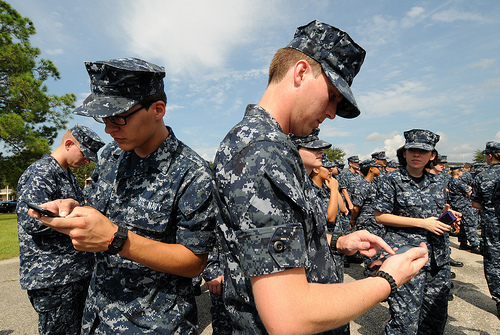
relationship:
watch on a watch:
[94, 217, 158, 287] [103, 225, 131, 255]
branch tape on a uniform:
[136, 198, 166, 209] [27, 55, 215, 335]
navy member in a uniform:
[371, 127, 463, 335] [373, 127, 453, 335]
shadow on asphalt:
[451, 242, 489, 332] [396, 235, 498, 335]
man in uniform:
[16, 126, 103, 334] [17, 126, 101, 334]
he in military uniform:
[30, 53, 220, 333] [86, 126, 213, 333]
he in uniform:
[212, 18, 425, 335] [209, 21, 434, 333]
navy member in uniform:
[371, 127, 463, 335] [373, 127, 453, 335]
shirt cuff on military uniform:
[233, 223, 313, 275] [216, 16, 382, 333]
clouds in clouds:
[12, 5, 498, 175] [12, 5, 499, 160]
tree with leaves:
[0, 0, 76, 184] [0, 0, 75, 182]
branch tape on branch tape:
[139, 195, 163, 212] [139, 195, 163, 212]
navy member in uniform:
[371, 127, 463, 335] [146, 19, 359, 296]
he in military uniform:
[212, 18, 425, 335] [216, 102, 337, 335]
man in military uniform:
[16, 126, 103, 334] [15, 156, 95, 291]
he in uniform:
[212, 18, 425, 335] [225, 80, 347, 263]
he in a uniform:
[212, 18, 425, 335] [209, 20, 361, 332]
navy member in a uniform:
[371, 127, 463, 335] [372, 129, 463, 333]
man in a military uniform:
[16, 126, 103, 334] [15, 156, 83, 335]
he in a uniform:
[30, 53, 220, 333] [76, 125, 219, 333]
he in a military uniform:
[212, 18, 425, 335] [216, 102, 337, 335]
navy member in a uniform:
[371, 127, 463, 335] [372, 163, 455, 333]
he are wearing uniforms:
[212, 18, 425, 335] [73, 140, 371, 317]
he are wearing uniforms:
[212, 18, 425, 335] [180, 102, 348, 333]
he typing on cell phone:
[30, 53, 220, 333] [26, 199, 61, 223]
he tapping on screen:
[203, 20, 425, 332] [367, 233, 421, 275]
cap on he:
[285, 6, 411, 111] [212, 18, 425, 335]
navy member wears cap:
[371, 127, 463, 335] [395, 128, 445, 150]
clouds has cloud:
[12, 5, 499, 160] [407, 5, 423, 15]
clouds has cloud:
[12, 5, 499, 160] [476, 55, 499, 71]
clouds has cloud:
[12, 5, 499, 160] [353, 80, 452, 112]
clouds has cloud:
[12, 5, 499, 160] [116, 3, 277, 73]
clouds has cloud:
[12, 5, 499, 160] [209, 91, 229, 101]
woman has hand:
[307, 152, 349, 237] [321, 173, 340, 189]